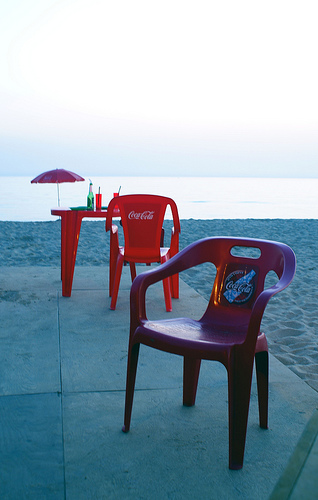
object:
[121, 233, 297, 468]
chair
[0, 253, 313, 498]
beach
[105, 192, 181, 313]
chair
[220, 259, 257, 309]
coca cola logo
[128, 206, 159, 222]
coca cola logo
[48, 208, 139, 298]
table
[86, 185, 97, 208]
bottle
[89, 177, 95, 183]
straw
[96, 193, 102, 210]
tumbler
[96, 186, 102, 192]
straw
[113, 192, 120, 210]
tumbler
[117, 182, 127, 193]
straw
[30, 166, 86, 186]
umbrella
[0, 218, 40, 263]
sand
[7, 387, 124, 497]
floor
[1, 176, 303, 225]
water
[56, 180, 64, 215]
rod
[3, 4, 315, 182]
sky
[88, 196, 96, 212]
label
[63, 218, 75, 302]
leg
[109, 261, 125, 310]
leg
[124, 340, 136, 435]
leg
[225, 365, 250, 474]
leg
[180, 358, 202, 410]
leg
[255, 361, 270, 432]
leg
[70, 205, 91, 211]
plate